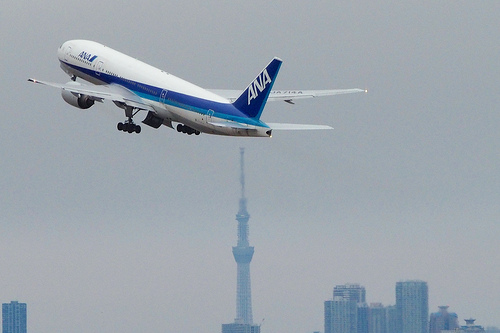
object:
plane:
[26, 38, 367, 137]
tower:
[214, 146, 267, 332]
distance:
[2, 119, 498, 331]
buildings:
[323, 279, 498, 333]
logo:
[74, 46, 100, 64]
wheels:
[116, 121, 141, 134]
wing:
[26, 77, 152, 113]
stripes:
[67, 57, 285, 121]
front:
[55, 38, 88, 74]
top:
[58, 38, 232, 99]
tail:
[231, 56, 297, 142]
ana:
[247, 68, 272, 106]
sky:
[0, 1, 499, 330]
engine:
[60, 80, 95, 109]